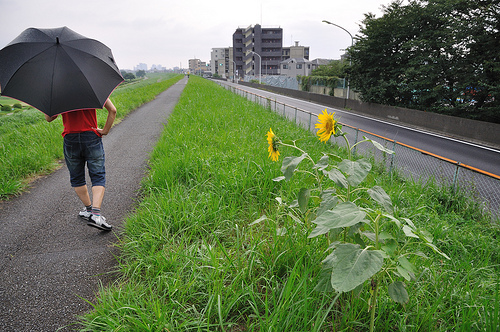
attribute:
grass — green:
[1, 73, 498, 328]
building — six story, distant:
[230, 24, 283, 81]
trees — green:
[309, 0, 499, 124]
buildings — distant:
[188, 24, 349, 87]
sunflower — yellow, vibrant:
[264, 125, 286, 161]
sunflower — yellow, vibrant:
[313, 105, 341, 145]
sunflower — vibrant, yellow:
[264, 126, 284, 165]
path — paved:
[44, 74, 184, 285]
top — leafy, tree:
[352, 13, 480, 93]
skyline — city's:
[128, 60, 182, 76]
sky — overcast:
[37, 6, 433, 61]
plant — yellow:
[265, 101, 451, 321]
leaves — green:
[244, 167, 475, 317]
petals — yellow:
[320, 137, 330, 144]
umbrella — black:
[3, 17, 123, 125]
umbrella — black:
[11, 23, 131, 116]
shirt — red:
[60, 115, 101, 131]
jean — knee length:
[58, 131, 106, 189]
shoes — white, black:
[77, 205, 116, 232]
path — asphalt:
[15, 71, 181, 302]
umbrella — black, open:
[13, 24, 125, 121]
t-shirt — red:
[54, 112, 103, 135]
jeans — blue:
[63, 133, 109, 184]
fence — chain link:
[196, 71, 499, 231]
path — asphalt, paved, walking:
[1, 74, 190, 330]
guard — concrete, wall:
[204, 73, 499, 150]